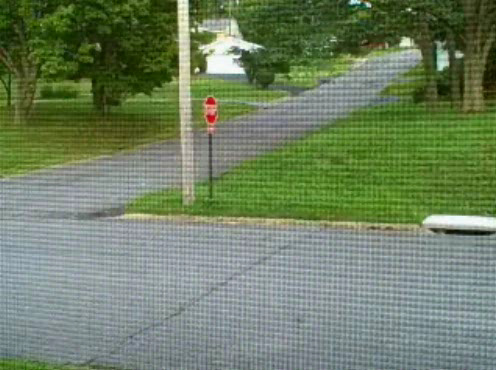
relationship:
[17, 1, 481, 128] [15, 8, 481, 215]
trees next to field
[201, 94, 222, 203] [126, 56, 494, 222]
sign on grass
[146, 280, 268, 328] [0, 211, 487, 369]
crack in road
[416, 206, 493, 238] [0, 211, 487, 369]
thing on side of road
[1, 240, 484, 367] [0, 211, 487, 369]
asphalt roads running through road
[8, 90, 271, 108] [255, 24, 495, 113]
small path by trees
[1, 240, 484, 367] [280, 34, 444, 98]
asphalt roads on hill